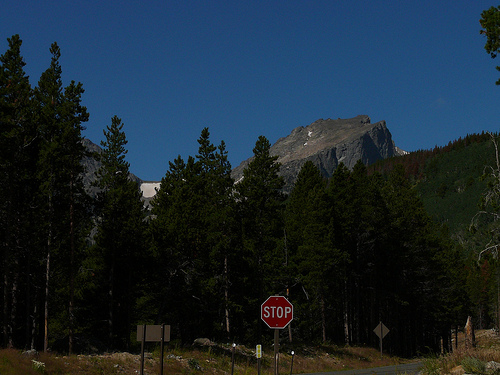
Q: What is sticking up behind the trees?
A: The top of a rocky mountain.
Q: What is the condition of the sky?
A: Dark blue and clear.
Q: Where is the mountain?
A: Behind the trees.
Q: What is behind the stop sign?
A: Trees.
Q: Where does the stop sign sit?
A: On a small grassy hill.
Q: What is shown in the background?
A: A large rock mountain.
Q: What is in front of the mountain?
A: A row of trees.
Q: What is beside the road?
A: A stop sign.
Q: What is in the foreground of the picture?
A: A road.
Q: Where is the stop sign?
A: Center foreground.